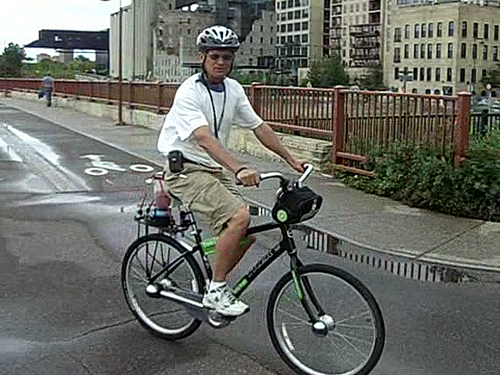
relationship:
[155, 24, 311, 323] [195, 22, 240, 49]
man wearing a helmet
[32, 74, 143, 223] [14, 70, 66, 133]
man walking holding a bag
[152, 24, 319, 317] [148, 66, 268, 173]
man wearing a shirt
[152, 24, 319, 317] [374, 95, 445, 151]
man by a section of fence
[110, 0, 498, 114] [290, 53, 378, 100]
buildings in city on background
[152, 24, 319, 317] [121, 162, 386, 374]
man on a bike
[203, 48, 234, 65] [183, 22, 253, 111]
glasses on a man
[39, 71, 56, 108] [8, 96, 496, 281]
man walking on sidewalk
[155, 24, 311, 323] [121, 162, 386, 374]
man riding a bike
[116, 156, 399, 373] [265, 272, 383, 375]
bicycle front tire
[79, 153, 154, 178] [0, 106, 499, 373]
markings on street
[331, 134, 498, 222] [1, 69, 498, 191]
bushes near fence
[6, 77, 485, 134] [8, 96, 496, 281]
fence near sidewalk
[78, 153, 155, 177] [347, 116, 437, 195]
markings on ground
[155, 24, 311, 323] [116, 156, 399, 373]
man on a bicycle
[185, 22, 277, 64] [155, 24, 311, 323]
helmet on a man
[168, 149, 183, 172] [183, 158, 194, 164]
cell phone on a belt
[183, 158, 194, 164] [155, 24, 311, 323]
belt on man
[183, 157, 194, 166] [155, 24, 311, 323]
belt on man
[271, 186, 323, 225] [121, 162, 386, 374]
bag on bike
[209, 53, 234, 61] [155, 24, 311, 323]
glasses on man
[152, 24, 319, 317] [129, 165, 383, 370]
man on bicycle